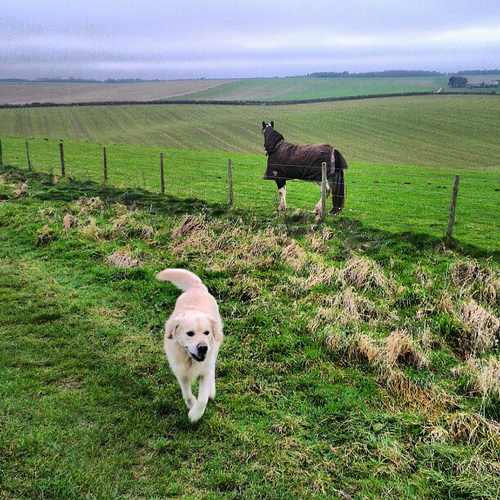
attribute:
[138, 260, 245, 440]
dog — tan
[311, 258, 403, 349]
grass — dead, brown, pile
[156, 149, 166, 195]
post — fence, wooden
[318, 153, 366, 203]
tail — large, hairy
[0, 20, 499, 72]
clouds — white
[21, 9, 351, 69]
clouds — white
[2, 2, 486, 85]
sky — blue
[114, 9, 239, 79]
sky — blue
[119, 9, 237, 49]
sky — blue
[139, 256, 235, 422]
dog — fluffy, white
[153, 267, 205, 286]
tail — large, hairy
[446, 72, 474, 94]
tree — large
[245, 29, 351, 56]
clouds — white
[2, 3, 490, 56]
sky — blue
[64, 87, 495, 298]
pasture — rolling, green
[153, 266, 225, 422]
dog — furry, white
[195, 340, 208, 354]
nose — white black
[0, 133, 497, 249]
fence — large, wire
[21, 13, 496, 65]
clouds — white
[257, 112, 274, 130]
ears — brown, little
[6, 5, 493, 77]
sky — blue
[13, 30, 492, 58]
clouds — white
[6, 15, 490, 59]
clouds — white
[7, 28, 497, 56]
clouds — white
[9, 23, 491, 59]
clouds — white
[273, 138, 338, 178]
blanket — brown